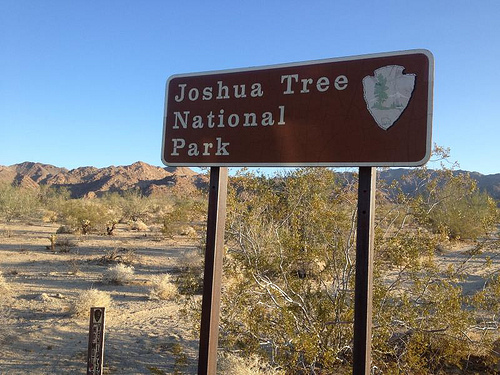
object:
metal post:
[351, 165, 377, 374]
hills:
[157, 172, 199, 196]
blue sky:
[0, 0, 499, 178]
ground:
[0, 210, 500, 375]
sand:
[0, 208, 192, 375]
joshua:
[174, 82, 264, 103]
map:
[362, 64, 417, 130]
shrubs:
[55, 196, 118, 235]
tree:
[218, 208, 475, 375]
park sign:
[158, 50, 434, 166]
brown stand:
[197, 158, 230, 373]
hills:
[87, 172, 136, 195]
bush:
[193, 168, 500, 375]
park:
[0, 159, 500, 375]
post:
[88, 308, 104, 373]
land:
[0, 200, 500, 375]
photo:
[0, 0, 500, 375]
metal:
[356, 160, 376, 371]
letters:
[172, 110, 190, 131]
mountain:
[0, 159, 204, 205]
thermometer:
[90, 303, 106, 372]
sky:
[0, 0, 500, 177]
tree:
[285, 168, 345, 288]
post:
[197, 161, 226, 375]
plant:
[102, 263, 134, 284]